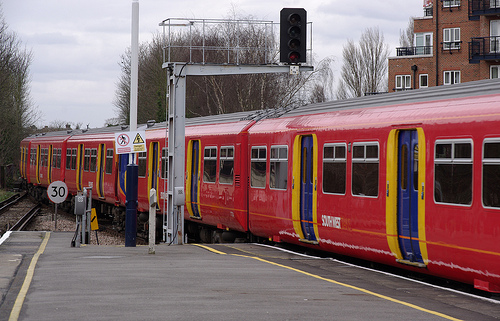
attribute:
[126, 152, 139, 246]
pole — blue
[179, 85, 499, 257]
train — red, yellow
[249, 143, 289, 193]
windows — Closed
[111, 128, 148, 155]
sign — white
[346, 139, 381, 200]
windows — Closed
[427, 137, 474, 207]
windows — Closed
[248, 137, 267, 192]
windows — Closed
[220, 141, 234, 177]
windows — Closed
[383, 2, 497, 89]
building — brick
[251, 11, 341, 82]
light — off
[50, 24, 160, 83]
sky — blue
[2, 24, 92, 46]
cloud — white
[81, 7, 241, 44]
cloud — white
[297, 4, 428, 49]
cloud — white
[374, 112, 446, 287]
door — yellow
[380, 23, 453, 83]
balcony — Empty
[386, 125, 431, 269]
door — blue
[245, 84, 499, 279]
train — yellow, red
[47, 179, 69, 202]
sign — red , white 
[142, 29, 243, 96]
tree — leafless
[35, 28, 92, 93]
sky — cloudy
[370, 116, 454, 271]
door — blue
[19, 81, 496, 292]
train — red, yellow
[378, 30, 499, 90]
building — brick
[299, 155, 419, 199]
train — yellow, red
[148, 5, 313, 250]
metal light — traffic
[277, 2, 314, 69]
traffic signal — black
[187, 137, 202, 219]
door — blue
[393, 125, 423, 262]
door — blue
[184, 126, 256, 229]
train — red, yellow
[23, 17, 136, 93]
clouds — white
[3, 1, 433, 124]
sky — blue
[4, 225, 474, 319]
waiting area — concrete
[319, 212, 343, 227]
lettering — white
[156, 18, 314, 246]
structure — metal, silver